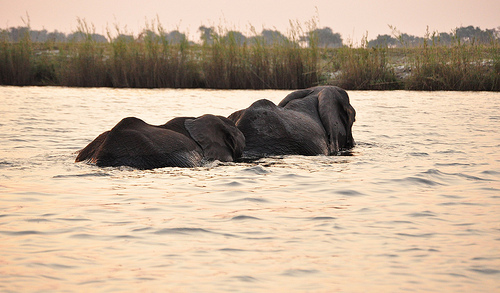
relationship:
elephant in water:
[75, 114, 246, 170] [0, 86, 499, 293]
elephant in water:
[227, 85, 356, 156] [0, 86, 499, 293]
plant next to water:
[107, 31, 142, 89] [0, 86, 499, 293]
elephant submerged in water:
[227, 85, 356, 156] [0, 86, 499, 293]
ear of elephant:
[184, 114, 236, 162] [75, 114, 246, 170]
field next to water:
[0, 43, 499, 91] [0, 86, 499, 293]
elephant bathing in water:
[75, 114, 246, 170] [0, 86, 499, 293]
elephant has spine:
[75, 114, 246, 170] [94, 118, 194, 161]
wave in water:
[334, 189, 364, 196] [0, 86, 499, 293]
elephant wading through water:
[75, 114, 246, 170] [0, 86, 499, 293]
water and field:
[0, 86, 499, 293] [0, 43, 499, 91]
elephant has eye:
[75, 114, 246, 170] [242, 138, 246, 150]